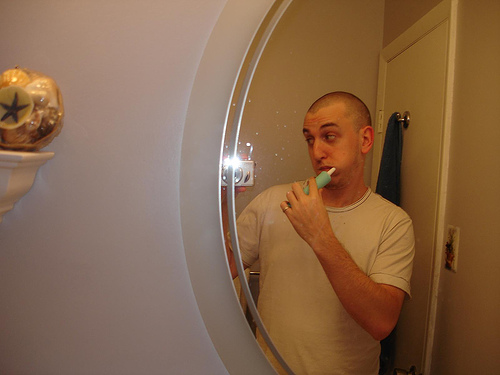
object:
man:
[220, 91, 412, 374]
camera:
[220, 160, 253, 187]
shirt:
[224, 179, 415, 373]